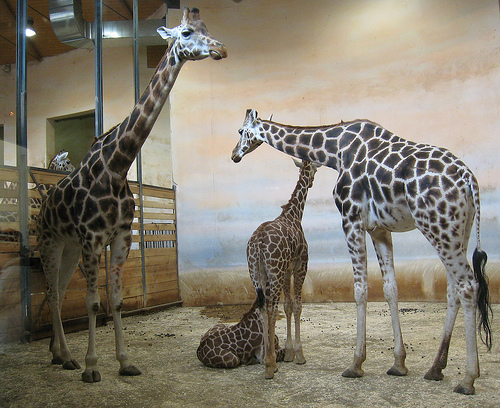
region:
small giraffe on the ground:
[194, 284, 291, 392]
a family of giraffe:
[20, 1, 497, 402]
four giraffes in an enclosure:
[20, 2, 492, 403]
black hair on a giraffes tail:
[472, 247, 499, 351]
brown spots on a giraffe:
[65, 191, 101, 219]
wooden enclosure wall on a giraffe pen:
[145, 196, 175, 283]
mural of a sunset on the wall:
[186, 106, 218, 284]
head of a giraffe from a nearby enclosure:
[40, 146, 74, 176]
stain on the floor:
[195, 294, 235, 324]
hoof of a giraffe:
[72, 361, 104, 387]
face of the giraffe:
[228, 108, 271, 169]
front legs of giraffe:
[341, 258, 429, 379]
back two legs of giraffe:
[418, 303, 498, 406]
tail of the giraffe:
[462, 250, 498, 325]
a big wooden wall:
[138, 183, 208, 331]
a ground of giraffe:
[17, 22, 497, 339]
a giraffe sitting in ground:
[196, 301, 278, 395]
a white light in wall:
[75, 18, 145, 60]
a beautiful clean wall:
[172, 28, 494, 278]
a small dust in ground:
[397, 292, 428, 311]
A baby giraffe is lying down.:
[196, 290, 284, 367]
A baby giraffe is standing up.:
[247, 160, 322, 379]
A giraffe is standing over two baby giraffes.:
[231, 109, 493, 393]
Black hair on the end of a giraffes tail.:
[471, 248, 492, 352]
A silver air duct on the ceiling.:
[48, 1, 168, 46]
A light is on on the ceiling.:
[23, 14, 36, 37]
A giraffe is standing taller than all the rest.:
[36, 5, 228, 382]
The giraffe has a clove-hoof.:
[81, 368, 102, 383]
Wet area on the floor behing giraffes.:
[200, 302, 285, 324]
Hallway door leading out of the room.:
[45, 108, 97, 170]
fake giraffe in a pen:
[25, 2, 239, 393]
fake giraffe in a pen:
[243, 152, 335, 381]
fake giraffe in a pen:
[192, 279, 274, 372]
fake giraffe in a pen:
[225, 103, 495, 404]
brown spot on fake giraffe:
[373, 163, 398, 186]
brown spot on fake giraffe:
[392, 177, 409, 202]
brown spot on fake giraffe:
[309, 128, 327, 150]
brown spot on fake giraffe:
[281, 132, 301, 146]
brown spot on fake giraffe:
[116, 132, 145, 158]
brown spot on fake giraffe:
[141, 92, 156, 117]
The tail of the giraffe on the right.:
[473, 178, 491, 347]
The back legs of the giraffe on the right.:
[430, 216, 479, 393]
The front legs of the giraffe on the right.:
[349, 233, 409, 376]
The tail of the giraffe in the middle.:
[251, 243, 265, 308]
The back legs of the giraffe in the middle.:
[254, 273, 279, 377]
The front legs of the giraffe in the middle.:
[282, 267, 306, 366]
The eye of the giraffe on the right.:
[234, 125, 244, 135]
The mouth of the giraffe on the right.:
[227, 150, 239, 161]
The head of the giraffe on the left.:
[160, 10, 227, 64]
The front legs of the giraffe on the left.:
[85, 242, 140, 378]